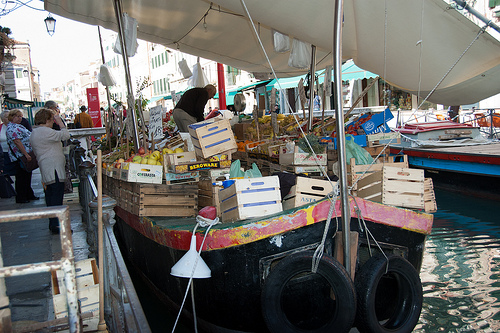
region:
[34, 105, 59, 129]
the head of a woman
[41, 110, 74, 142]
the arm of a woman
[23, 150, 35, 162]
the hand of a woman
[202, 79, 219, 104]
the head of a man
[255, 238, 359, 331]
a black tire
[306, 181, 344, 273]
a white rope tied to a tire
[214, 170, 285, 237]
a brown wooden crate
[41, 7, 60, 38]
a street lamp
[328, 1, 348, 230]
a silver metal pole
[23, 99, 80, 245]
a woman on the dock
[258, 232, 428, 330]
tires hanging on boat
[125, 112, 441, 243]
wooden boxes on boat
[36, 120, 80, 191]
large khaki woman's shirt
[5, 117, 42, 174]
large floral woman's shirt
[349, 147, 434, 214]
small wooden produce box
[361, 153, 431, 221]
empty wooden produce box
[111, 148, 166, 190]
cardboard full produce box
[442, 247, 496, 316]
this is rippling water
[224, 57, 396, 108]
a green building awning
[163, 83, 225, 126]
a large black man's shirt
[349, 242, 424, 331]
A rubber tire on the back of a boat.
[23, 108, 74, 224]
a woman standing on the side of a boat.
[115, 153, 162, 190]
a box of fruit for sale.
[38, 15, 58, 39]
A suspended light.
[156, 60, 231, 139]
A man standing on a boat of fruit.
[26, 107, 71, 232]
A woman standing on the side of a boat.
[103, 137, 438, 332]
A large boat filled with fruit.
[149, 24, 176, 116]
A tall multi story building.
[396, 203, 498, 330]
A body of water.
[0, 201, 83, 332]
rusted metal bars.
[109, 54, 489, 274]
wow a messy boat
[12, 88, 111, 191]
a group of people watching the boat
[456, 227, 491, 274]
water the boat is floating on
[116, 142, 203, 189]
a box of fruit for sale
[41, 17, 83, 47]
a lamp that is turned off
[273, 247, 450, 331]
two tires hanging from the boat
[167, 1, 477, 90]
the canopy of the boat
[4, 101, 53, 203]
a lady watching the boat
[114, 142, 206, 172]
apples that are on the boat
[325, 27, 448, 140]
the string holding the top of the canopy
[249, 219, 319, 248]
RED, YELLOW, BLACK, WHITE, GREY PAINT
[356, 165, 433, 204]
EMPATY WOODEN FRUIT CRATES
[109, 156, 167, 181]
FRESH PRODUCE, APPLES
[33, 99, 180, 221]
DOCK SIDE PRODUCE MARKET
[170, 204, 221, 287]
FUNNEL ATTACHED TO THE BOAT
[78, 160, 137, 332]
IRON RAILING ALONG DOCK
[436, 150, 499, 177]
BLUE AND RED TRIM STRIPES ON BOAT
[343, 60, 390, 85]
TEAL AND TAN AWINGS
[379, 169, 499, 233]
BOATS DOCKED IN CALM WATER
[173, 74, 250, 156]
MAN WEIGHING PRODUCE